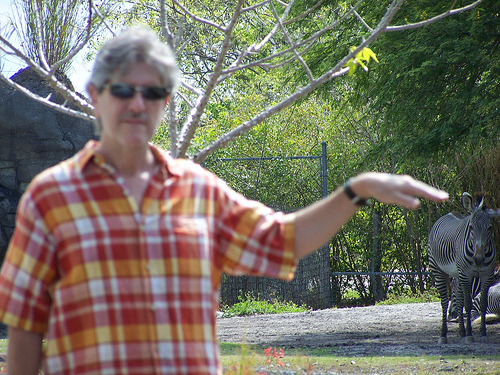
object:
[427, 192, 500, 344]
zebra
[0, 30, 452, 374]
man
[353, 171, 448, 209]
hand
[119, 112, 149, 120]
mustache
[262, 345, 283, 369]
flowers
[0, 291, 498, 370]
ground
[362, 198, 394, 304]
tree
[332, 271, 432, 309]
gate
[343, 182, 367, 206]
watch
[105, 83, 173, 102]
sunglasses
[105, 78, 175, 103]
glasses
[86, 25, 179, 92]
gray hair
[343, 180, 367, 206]
watch band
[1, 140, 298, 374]
orange-red shirt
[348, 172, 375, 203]
wrist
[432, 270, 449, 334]
legs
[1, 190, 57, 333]
sleeve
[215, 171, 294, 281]
sleeve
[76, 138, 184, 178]
collar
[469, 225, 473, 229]
eyes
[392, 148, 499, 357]
shade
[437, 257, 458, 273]
belly